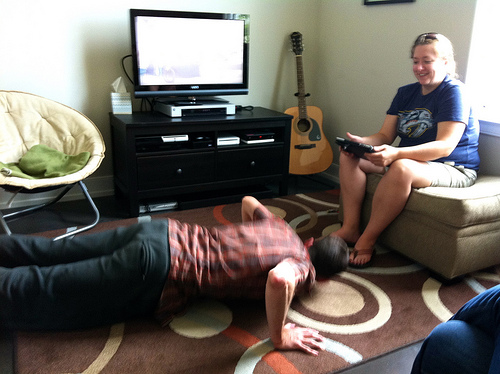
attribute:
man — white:
[7, 189, 347, 351]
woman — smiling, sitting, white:
[337, 19, 475, 270]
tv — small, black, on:
[120, 4, 258, 104]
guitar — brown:
[285, 25, 336, 175]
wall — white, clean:
[1, 1, 492, 167]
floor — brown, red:
[3, 182, 492, 373]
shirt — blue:
[384, 80, 478, 167]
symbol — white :
[399, 108, 433, 138]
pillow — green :
[17, 144, 84, 176]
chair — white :
[0, 88, 103, 244]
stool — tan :
[419, 190, 497, 270]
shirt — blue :
[388, 80, 488, 167]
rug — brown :
[352, 297, 421, 333]